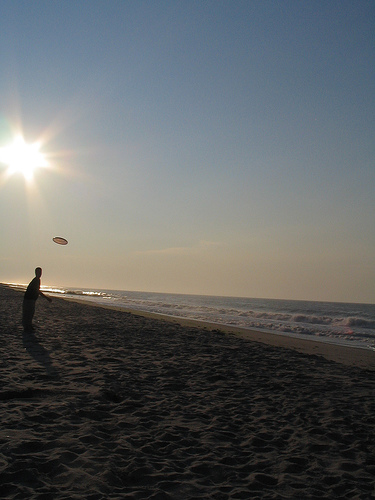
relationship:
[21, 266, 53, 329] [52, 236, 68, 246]
person throwing frisbee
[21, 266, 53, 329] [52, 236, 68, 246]
person playing frisbee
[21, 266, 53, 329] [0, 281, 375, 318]
person in ocean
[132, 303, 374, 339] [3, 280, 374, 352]
waves in ocean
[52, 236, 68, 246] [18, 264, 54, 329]
frisbee by person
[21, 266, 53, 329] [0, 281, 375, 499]
person standing on sand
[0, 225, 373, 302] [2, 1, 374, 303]
clouds in sky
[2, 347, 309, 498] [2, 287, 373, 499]
footprints on sand